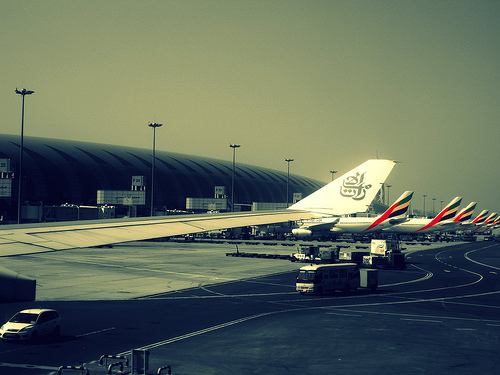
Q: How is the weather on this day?
A: It is overcast.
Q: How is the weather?
A: It is overcast.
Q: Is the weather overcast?
A: Yes, it is overcast.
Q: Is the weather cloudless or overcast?
A: It is overcast.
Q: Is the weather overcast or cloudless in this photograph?
A: It is overcast.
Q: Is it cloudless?
A: No, it is overcast.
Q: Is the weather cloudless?
A: No, it is overcast.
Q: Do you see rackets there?
A: No, there are no rackets.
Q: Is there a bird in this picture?
A: No, there are no birds.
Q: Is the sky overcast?
A: Yes, the sky is overcast.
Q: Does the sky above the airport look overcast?
A: Yes, the sky is overcast.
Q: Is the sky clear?
A: No, the sky is overcast.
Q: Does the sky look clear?
A: No, the sky is overcast.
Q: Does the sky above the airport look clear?
A: No, the sky is overcast.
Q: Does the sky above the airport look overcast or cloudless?
A: The sky is overcast.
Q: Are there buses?
A: Yes, there is a bus.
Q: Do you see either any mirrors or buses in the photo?
A: Yes, there is a bus.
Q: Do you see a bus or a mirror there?
A: Yes, there is a bus.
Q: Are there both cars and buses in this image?
A: Yes, there are both a bus and a car.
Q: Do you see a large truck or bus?
A: Yes, there is a large bus.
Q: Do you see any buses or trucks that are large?
A: Yes, the bus is large.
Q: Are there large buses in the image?
A: Yes, there is a large bus.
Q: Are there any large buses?
A: Yes, there is a large bus.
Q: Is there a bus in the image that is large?
A: Yes, there is a bus that is large.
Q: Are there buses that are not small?
A: Yes, there is a large bus.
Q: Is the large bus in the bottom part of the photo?
A: Yes, the bus is in the bottom of the image.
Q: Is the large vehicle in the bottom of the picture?
A: Yes, the bus is in the bottom of the image.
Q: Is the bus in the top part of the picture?
A: No, the bus is in the bottom of the image.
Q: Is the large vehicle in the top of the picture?
A: No, the bus is in the bottom of the image.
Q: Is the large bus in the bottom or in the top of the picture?
A: The bus is in the bottom of the image.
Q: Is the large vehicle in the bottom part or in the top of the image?
A: The bus is in the bottom of the image.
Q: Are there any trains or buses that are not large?
A: No, there is a bus but it is large.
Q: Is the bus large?
A: Yes, the bus is large.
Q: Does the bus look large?
A: Yes, the bus is large.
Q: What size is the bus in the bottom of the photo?
A: The bus is large.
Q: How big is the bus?
A: The bus is large.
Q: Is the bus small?
A: No, the bus is large.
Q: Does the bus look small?
A: No, the bus is large.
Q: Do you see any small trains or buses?
A: No, there is a bus but it is large.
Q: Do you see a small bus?
A: No, there is a bus but it is large.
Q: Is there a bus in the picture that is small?
A: No, there is a bus but it is large.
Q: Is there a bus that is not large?
A: No, there is a bus but it is large.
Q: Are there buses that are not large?
A: No, there is a bus but it is large.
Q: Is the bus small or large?
A: The bus is large.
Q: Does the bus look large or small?
A: The bus is large.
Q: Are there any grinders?
A: No, there are no grinders.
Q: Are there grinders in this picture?
A: No, there are no grinders.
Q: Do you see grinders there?
A: No, there are no grinders.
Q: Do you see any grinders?
A: No, there are no grinders.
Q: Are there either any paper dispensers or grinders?
A: No, there are no grinders or paper dispensers.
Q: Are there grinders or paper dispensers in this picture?
A: No, there are no grinders or paper dispensers.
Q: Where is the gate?
A: The gate is at the airport.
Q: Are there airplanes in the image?
A: Yes, there are airplanes.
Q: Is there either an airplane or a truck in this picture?
A: Yes, there are airplanes.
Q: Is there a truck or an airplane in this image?
A: Yes, there are airplanes.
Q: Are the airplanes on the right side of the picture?
A: Yes, the airplanes are on the right of the image.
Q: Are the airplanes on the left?
A: No, the airplanes are on the right of the image.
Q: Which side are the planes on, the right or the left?
A: The planes are on the right of the image.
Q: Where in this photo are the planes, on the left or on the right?
A: The planes are on the right of the image.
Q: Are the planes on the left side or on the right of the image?
A: The planes are on the right of the image.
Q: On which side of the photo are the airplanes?
A: The airplanes are on the right of the image.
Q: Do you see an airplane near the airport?
A: Yes, there are airplanes near the airport.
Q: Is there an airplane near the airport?
A: Yes, there are airplanes near the airport.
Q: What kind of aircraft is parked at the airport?
A: The aircraft is airplanes.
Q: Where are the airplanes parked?
A: The airplanes are parked at the airport.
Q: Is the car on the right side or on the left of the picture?
A: The car is on the left of the image.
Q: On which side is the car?
A: The car is on the left of the image.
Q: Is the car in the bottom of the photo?
A: Yes, the car is in the bottom of the image.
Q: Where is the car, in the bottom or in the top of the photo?
A: The car is in the bottom of the image.